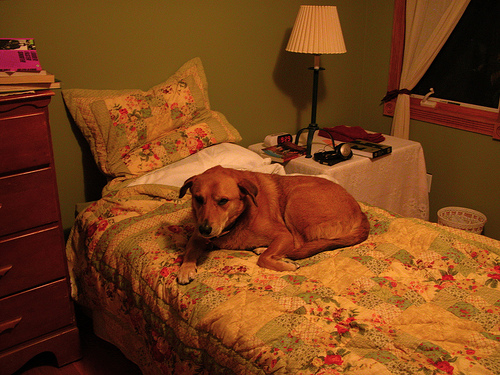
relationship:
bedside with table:
[249, 121, 437, 221] [259, 125, 425, 228]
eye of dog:
[192, 193, 206, 204] [166, 161, 371, 292]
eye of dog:
[216, 195, 228, 205] [166, 161, 371, 292]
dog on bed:
[166, 161, 371, 292] [65, 141, 493, 369]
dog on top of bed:
[153, 157, 381, 276] [65, 141, 493, 369]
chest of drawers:
[1, 85, 89, 374] [0, 110, 82, 359]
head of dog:
[177, 165, 257, 240] [166, 161, 371, 292]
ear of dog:
[235, 176, 261, 207] [166, 161, 371, 292]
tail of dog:
[283, 230, 374, 261] [166, 161, 371, 292]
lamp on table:
[287, 2, 344, 151] [269, 117, 441, 229]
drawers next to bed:
[0, 110, 82, 359] [72, 103, 459, 366]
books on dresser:
[11, 37, 63, 117] [6, 52, 123, 360]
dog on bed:
[166, 161, 371, 292] [66, 158, 498, 374]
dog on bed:
[176, 164, 370, 271] [65, 141, 493, 369]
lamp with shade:
[288, 4, 348, 156] [278, 2, 369, 62]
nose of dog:
[199, 220, 213, 237] [176, 164, 370, 271]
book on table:
[257, 138, 309, 165] [246, 122, 433, 222]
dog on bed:
[152, 148, 378, 302] [87, 130, 484, 360]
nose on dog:
[199, 220, 213, 237] [166, 161, 371, 292]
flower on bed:
[436, 270, 457, 282] [65, 141, 493, 369]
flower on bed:
[331, 317, 352, 334] [65, 141, 493, 369]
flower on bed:
[435, 360, 454, 373] [65, 141, 493, 369]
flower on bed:
[323, 352, 343, 366] [65, 141, 493, 369]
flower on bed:
[264, 284, 272, 291] [65, 141, 493, 369]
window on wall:
[379, 1, 498, 141] [297, 4, 484, 244]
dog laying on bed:
[166, 161, 371, 292] [65, 141, 493, 369]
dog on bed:
[166, 161, 371, 292] [60, 52, 496, 373]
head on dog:
[172, 163, 246, 230] [183, 154, 267, 261]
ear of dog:
[235, 175, 265, 212] [176, 153, 382, 285]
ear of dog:
[173, 174, 197, 199] [176, 153, 382, 285]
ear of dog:
[177, 170, 206, 209] [166, 161, 371, 292]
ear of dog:
[236, 177, 259, 208] [177, 163, 370, 284]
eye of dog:
[191, 193, 205, 210] [166, 161, 371, 292]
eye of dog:
[218, 190, 226, 207] [166, 161, 371, 292]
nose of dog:
[199, 220, 213, 237] [177, 163, 370, 284]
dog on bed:
[165, 163, 374, 275] [65, 141, 493, 369]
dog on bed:
[177, 163, 370, 284] [65, 141, 493, 369]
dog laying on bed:
[177, 163, 370, 284] [65, 141, 493, 369]